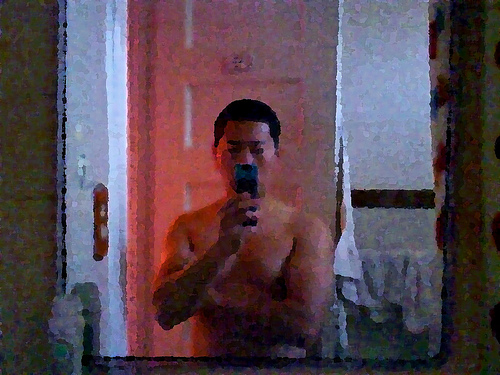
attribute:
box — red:
[94, 183, 110, 257]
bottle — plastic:
[42, 285, 95, 367]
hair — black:
[214, 98, 281, 154]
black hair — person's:
[204, 97, 284, 154]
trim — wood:
[351, 189, 431, 208]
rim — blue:
[440, 222, 456, 367]